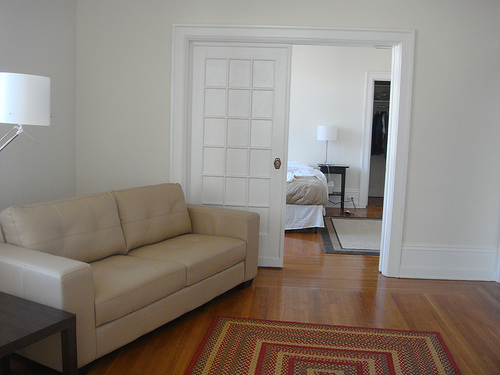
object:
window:
[204, 57, 229, 89]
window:
[227, 57, 253, 91]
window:
[249, 55, 276, 90]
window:
[201, 84, 229, 119]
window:
[225, 86, 253, 122]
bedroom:
[171, 17, 400, 274]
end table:
[0, 289, 78, 375]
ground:
[419, 132, 437, 153]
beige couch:
[0, 169, 259, 374]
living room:
[0, 0, 499, 375]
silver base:
[323, 141, 331, 164]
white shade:
[316, 124, 341, 142]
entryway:
[163, 15, 409, 284]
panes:
[203, 57, 273, 142]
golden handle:
[273, 156, 283, 170]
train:
[13, 179, 272, 370]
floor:
[67, 206, 499, 373]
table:
[0, 291, 79, 373]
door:
[171, 26, 290, 268]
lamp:
[0, 70, 52, 128]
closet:
[366, 68, 411, 196]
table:
[324, 165, 348, 216]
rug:
[324, 215, 384, 262]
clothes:
[368, 109, 391, 155]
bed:
[284, 159, 329, 232]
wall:
[0, 2, 498, 279]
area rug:
[188, 314, 457, 375]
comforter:
[281, 163, 327, 205]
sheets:
[285, 206, 327, 234]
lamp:
[315, 121, 337, 164]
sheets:
[287, 165, 325, 207]